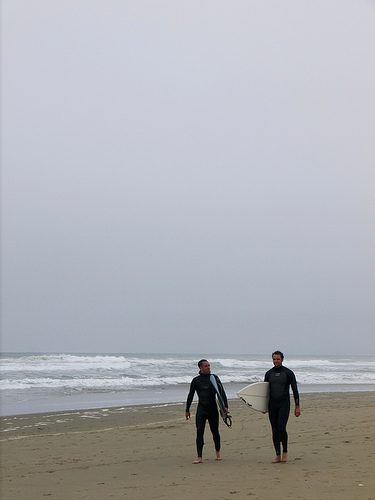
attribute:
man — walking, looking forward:
[266, 351, 301, 463]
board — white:
[234, 379, 272, 413]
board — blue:
[214, 396, 233, 427]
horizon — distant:
[2, 341, 373, 361]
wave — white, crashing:
[6, 355, 128, 367]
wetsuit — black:
[262, 366, 298, 457]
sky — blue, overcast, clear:
[0, 3, 375, 361]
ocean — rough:
[4, 351, 374, 414]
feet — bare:
[270, 450, 291, 463]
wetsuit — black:
[185, 372, 226, 459]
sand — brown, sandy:
[4, 393, 372, 496]